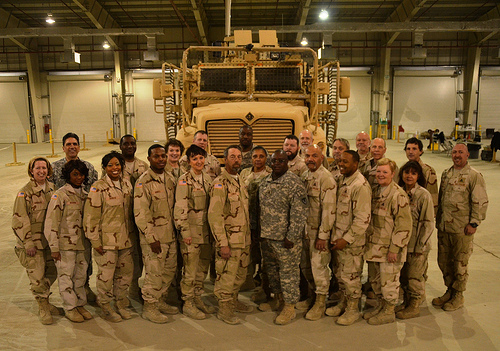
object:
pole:
[11, 141, 17, 166]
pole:
[51, 138, 55, 155]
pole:
[82, 134, 86, 151]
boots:
[362, 299, 397, 324]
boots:
[297, 287, 330, 320]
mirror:
[340, 76, 351, 99]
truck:
[153, 29, 350, 162]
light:
[319, 10, 331, 22]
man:
[209, 145, 260, 325]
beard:
[226, 164, 245, 175]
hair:
[184, 144, 207, 160]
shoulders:
[16, 184, 32, 201]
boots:
[30, 287, 63, 326]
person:
[364, 159, 413, 326]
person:
[429, 142, 490, 311]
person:
[10, 155, 57, 325]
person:
[395, 162, 436, 319]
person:
[300, 144, 336, 321]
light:
[301, 37, 308, 45]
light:
[101, 39, 110, 51]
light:
[45, 12, 56, 25]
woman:
[10, 157, 61, 325]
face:
[32, 160, 49, 182]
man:
[330, 149, 372, 324]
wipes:
[195, 83, 309, 106]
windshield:
[193, 63, 308, 95]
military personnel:
[12, 128, 489, 323]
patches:
[15, 190, 28, 199]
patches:
[50, 192, 60, 199]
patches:
[87, 183, 104, 193]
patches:
[134, 180, 146, 191]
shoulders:
[13, 180, 38, 200]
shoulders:
[46, 181, 70, 207]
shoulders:
[88, 175, 110, 193]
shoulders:
[135, 166, 157, 187]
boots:
[256, 291, 302, 326]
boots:
[212, 291, 253, 326]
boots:
[181, 288, 215, 319]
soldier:
[173, 143, 213, 320]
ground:
[0, 142, 500, 351]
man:
[255, 149, 307, 325]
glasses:
[270, 158, 284, 162]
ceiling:
[0, 0, 499, 70]